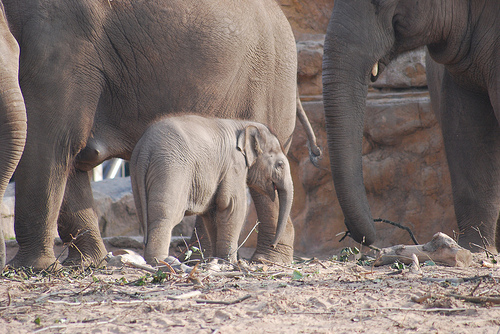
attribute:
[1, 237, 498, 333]
ground — light brown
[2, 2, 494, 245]
elephants — several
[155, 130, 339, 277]
elephant — large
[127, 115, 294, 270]
elephant — small, grey, gray, young, baby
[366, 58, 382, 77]
tusk — white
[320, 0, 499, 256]
elephant — adult, gray, baby, grey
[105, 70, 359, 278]
elephant — light brown, baby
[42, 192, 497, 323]
ground — grassy, dirty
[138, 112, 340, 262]
elephant — small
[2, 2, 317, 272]
elephant — gray, large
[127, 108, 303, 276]
elephant — Very large , lighter grey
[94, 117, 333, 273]
elephant — fuzzy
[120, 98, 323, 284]
elephant — grey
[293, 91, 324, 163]
tail — light grey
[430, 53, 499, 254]
elephant — large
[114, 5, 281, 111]
skin — wrinkled